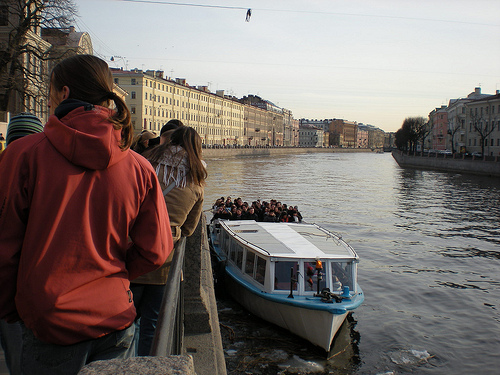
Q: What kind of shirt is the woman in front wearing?
A: A red sweater.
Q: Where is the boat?
A: On the water.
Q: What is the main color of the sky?
A: Gray.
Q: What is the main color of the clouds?
A: White.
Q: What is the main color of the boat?
A: White.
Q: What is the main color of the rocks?
A: Gray.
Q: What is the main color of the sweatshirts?
A: Red.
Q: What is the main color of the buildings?
A: Brown.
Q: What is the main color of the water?
A: Gray.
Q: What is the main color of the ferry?
A: White.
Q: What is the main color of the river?
A: Gray.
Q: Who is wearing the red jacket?
A: Woman on left.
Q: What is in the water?
A: Boat.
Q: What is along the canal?
A: Buildings.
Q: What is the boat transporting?
A: Travellers.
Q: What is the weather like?
A: Cool.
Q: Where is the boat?
A: Canal.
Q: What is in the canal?
A: Water.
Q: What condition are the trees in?
A: Barren.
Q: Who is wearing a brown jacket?
A: Woman by rail.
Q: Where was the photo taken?
A: River.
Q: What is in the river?
A: Boat.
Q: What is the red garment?
A: Hoodie.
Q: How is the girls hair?
A: Ponytail.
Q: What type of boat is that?
A: Tour boat.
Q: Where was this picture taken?
A: Italy.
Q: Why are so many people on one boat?
A: Sightseeing.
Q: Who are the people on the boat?
A: Tourist.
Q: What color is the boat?
A: White.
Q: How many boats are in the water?
A: One.